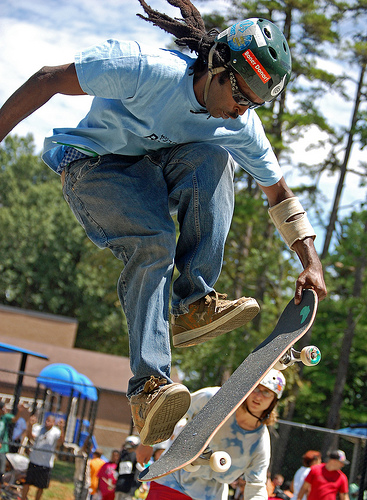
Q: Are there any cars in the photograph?
A: No, there are no cars.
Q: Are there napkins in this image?
A: No, there are no napkins.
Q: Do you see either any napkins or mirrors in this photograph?
A: No, there are no napkins or mirrors.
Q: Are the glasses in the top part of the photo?
A: Yes, the glasses are in the top of the image.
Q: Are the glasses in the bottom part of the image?
A: No, the glasses are in the top of the image.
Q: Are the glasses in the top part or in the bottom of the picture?
A: The glasses are in the top of the image.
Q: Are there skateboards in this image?
A: Yes, there is a skateboard.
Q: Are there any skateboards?
A: Yes, there is a skateboard.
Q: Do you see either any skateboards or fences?
A: Yes, there is a skateboard.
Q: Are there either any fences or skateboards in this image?
A: Yes, there is a skateboard.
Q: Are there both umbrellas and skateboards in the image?
A: No, there is a skateboard but no umbrellas.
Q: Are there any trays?
A: No, there are no trays.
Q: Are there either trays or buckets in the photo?
A: No, there are no trays or buckets.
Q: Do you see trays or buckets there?
A: No, there are no trays or buckets.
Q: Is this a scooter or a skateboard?
A: This is a skateboard.